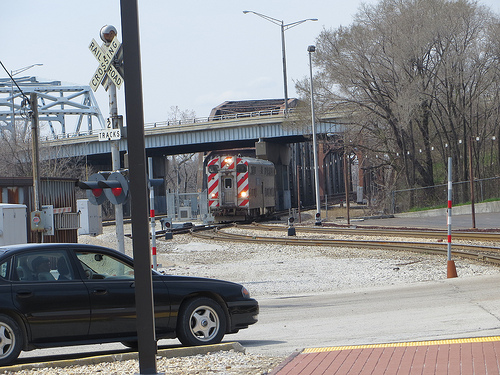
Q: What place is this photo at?
A: It is at the city.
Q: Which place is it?
A: It is a city.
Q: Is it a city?
A: Yes, it is a city.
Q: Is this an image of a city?
A: Yes, it is showing a city.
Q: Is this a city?
A: Yes, it is a city.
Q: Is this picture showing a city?
A: Yes, it is showing a city.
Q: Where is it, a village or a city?
A: It is a city.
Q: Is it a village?
A: No, it is a city.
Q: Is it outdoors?
A: Yes, it is outdoors.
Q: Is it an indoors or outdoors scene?
A: It is outdoors.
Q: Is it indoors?
A: No, it is outdoors.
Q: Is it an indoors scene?
A: No, it is outdoors.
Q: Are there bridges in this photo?
A: Yes, there is a bridge.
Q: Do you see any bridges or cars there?
A: Yes, there is a bridge.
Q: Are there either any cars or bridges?
A: Yes, there is a bridge.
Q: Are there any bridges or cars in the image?
A: Yes, there is a bridge.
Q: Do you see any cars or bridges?
A: Yes, there is a bridge.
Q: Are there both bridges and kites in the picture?
A: No, there is a bridge but no kites.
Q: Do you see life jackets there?
A: No, there are no life jackets.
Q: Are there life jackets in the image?
A: No, there are no life jackets.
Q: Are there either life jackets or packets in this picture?
A: No, there are no life jackets or packets.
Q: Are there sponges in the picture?
A: No, there are no sponges.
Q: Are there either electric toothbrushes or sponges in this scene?
A: No, there are no sponges or electric toothbrushes.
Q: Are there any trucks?
A: No, there are no trucks.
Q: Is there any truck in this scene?
A: No, there are no trucks.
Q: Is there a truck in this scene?
A: No, there are no trucks.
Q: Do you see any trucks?
A: No, there are no trucks.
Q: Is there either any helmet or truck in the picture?
A: No, there are no trucks or helmets.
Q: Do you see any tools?
A: No, there are no tools.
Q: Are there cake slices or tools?
A: No, there are no tools or cake slices.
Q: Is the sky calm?
A: Yes, the sky is calm.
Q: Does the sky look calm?
A: Yes, the sky is calm.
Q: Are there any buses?
A: No, there are no buses.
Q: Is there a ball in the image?
A: No, there are no balls.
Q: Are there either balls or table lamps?
A: No, there are no balls or table lamps.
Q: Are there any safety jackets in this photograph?
A: No, there are no safety jackets.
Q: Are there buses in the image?
A: No, there are no buses.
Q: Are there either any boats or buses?
A: No, there are no buses or boats.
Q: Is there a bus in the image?
A: No, there are no buses.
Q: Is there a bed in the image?
A: No, there are no beds.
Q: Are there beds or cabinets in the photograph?
A: No, there are no beds or cabinets.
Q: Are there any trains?
A: Yes, there is a train.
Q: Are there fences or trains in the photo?
A: Yes, there is a train.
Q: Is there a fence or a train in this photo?
A: Yes, there is a train.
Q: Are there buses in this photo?
A: No, there are no buses.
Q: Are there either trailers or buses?
A: No, there are no buses or trailers.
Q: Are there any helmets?
A: No, there are no helmets.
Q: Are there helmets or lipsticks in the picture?
A: No, there are no helmets or lipsticks.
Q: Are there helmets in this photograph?
A: No, there are no helmets.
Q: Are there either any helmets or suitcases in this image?
A: No, there are no helmets or suitcases.